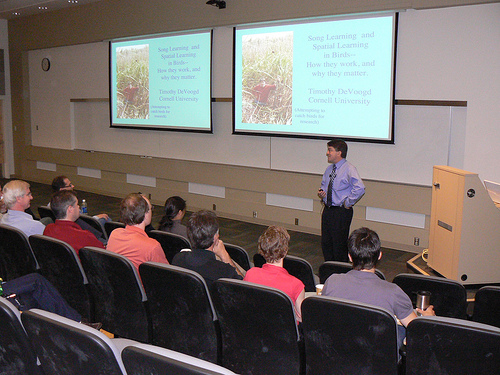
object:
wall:
[41, 15, 483, 190]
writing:
[298, 32, 380, 132]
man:
[317, 139, 366, 263]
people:
[0, 176, 438, 359]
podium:
[426, 164, 499, 285]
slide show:
[108, 11, 399, 145]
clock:
[41, 57, 50, 71]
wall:
[0, 0, 499, 260]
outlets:
[148, 194, 419, 246]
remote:
[319, 189, 324, 192]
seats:
[0, 204, 500, 374]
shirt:
[319, 157, 366, 208]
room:
[0, 0, 499, 373]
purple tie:
[327, 164, 337, 210]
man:
[106, 192, 170, 296]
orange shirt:
[106, 223, 171, 296]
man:
[0, 179, 47, 237]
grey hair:
[1, 179, 34, 210]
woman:
[243, 225, 305, 341]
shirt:
[243, 263, 305, 326]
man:
[42, 189, 107, 262]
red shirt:
[43, 219, 106, 260]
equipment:
[483, 180, 500, 208]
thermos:
[416, 291, 431, 317]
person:
[321, 227, 436, 364]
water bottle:
[80, 199, 88, 214]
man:
[172, 209, 243, 315]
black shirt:
[171, 248, 243, 301]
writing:
[143, 26, 385, 128]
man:
[157, 196, 190, 244]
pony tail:
[158, 206, 174, 231]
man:
[47, 176, 112, 227]